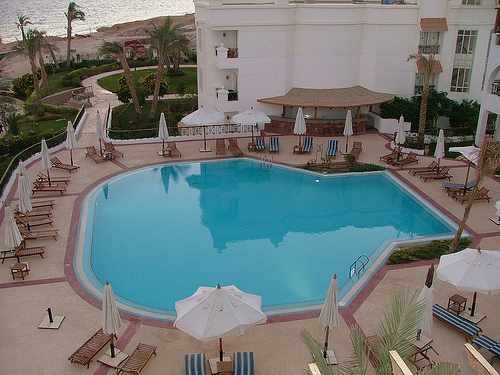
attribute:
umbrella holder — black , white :
[38, 305, 66, 331]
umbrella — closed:
[98, 275, 129, 349]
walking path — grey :
[74, 60, 195, 146]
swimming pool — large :
[81, 153, 453, 307]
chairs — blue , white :
[327, 136, 339, 158]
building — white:
[165, 4, 471, 146]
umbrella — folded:
[291, 105, 305, 137]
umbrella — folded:
[346, 108, 353, 134]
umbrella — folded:
[178, 269, 258, 331]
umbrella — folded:
[48, 111, 95, 176]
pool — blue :
[86, 157, 459, 315]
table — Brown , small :
[446, 292, 468, 317]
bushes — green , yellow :
[11, 56, 96, 98]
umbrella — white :
[143, 259, 274, 351]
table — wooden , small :
[445, 291, 467, 316]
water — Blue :
[83, 160, 450, 320]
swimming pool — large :
[59, 142, 476, 327]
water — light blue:
[72, 151, 465, 320]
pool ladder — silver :
[348, 253, 371, 277]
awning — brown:
[257, 84, 397, 107]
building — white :
[188, 2, 497, 147]